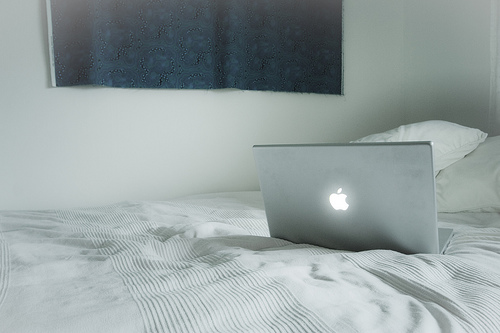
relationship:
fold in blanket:
[422, 292, 457, 329] [235, 245, 395, 322]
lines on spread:
[80, 205, 324, 331] [1, 185, 496, 327]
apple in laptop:
[328, 185, 349, 210] [251, 141, 453, 257]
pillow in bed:
[349, 118, 489, 177] [1, 110, 498, 322]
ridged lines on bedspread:
[77, 203, 329, 331] [1, 187, 497, 332]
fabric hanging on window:
[46, 2, 343, 96] [50, 0, 343, 95]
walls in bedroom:
[3, 2, 493, 189] [9, 15, 484, 318]